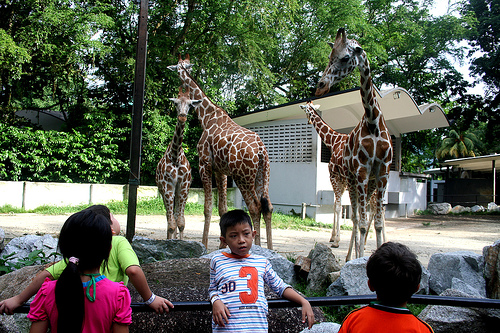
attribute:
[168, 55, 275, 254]
giraffe — standing, turned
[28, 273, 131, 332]
shirt — pink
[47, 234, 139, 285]
shirt — green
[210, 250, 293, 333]
shirt — striped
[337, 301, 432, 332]
shirt — orange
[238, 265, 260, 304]
number — orange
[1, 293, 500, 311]
bar — black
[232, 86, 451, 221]
building — white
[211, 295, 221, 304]
wristband — white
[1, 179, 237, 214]
fence — white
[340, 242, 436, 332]
boy — watching, looking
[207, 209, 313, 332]
boy — bored, leaning, standing, looking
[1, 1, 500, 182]
trees — behind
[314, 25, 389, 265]
giraffe — standing, interested, large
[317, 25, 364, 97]
head — large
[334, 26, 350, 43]
horns — pointing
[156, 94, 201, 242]
giraffe — small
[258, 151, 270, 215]
tail — long